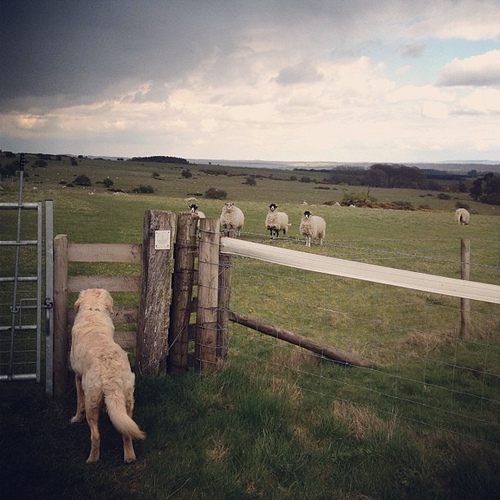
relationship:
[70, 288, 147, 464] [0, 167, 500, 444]
dog looking through fence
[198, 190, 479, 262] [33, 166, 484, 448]
sheep standing in field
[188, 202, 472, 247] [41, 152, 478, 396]
sheep standing in grass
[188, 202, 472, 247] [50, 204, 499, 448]
sheep behind fence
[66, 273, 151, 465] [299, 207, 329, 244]
dog watching sheep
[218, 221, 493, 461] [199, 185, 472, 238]
gate surrounding sheep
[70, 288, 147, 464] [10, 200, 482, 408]
dog standing gate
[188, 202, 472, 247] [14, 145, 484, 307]
sheep standing field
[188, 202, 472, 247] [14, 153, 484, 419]
sheep in field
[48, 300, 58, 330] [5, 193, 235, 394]
lock on gate